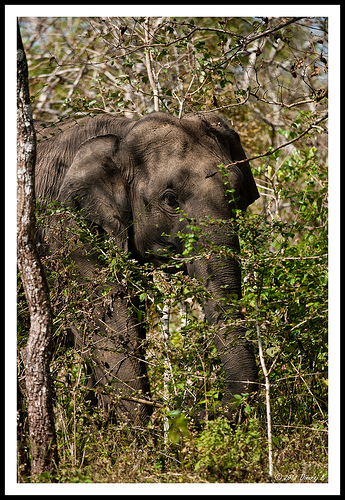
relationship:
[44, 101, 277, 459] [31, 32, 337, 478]
elephant in wild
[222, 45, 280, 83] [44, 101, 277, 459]
twigs behind elephant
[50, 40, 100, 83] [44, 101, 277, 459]
branches behind elephant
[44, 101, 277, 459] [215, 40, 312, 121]
elephant walking through trees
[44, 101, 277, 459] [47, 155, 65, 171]
elephant has wrinkles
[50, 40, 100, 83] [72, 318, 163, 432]
branches cover leg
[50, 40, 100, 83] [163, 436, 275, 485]
branches on ground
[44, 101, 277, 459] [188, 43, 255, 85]
elephant in woods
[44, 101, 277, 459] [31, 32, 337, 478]
elephant in photo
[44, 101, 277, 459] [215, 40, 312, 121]
elephant in trees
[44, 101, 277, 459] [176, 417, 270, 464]
elephant in bushes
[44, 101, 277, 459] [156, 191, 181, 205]
elephant has an eye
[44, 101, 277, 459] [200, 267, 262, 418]
elephant has a trunk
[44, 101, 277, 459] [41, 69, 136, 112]
elephant in forest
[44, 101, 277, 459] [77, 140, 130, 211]
elephant has ears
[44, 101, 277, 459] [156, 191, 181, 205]
elephant has eye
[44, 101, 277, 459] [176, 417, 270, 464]
elephant walking through bushes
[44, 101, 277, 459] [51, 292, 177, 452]
elephant has legs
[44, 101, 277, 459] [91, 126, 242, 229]
elephant has head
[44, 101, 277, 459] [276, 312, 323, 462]
elephant in brush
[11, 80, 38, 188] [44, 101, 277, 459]
tree next to elephant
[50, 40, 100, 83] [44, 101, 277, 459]
branches above elephant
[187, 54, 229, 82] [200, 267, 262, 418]
leaves below trunk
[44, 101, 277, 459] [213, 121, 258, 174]
elephant has an ear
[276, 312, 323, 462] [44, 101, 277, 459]
brush on side of elephant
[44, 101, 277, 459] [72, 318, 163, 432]
elephant has an leg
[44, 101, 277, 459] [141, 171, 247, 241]
elephant has a face